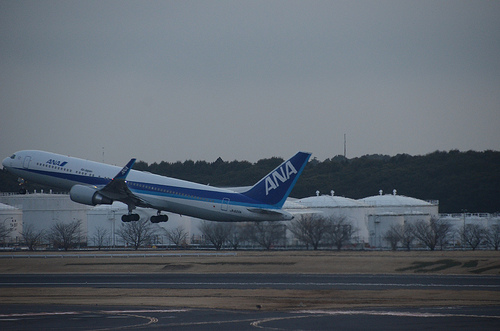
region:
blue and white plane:
[25, 145, 300, 241]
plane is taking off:
[7, 141, 294, 241]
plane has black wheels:
[112, 202, 183, 241]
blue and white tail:
[207, 146, 309, 210]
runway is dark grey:
[108, 250, 438, 294]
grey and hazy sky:
[226, 27, 358, 137]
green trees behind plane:
[245, 156, 479, 213]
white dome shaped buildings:
[306, 186, 416, 231]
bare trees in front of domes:
[13, 216, 468, 249]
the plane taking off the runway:
[9, 142, 311, 236]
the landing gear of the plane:
[122, 208, 163, 233]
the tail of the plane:
[236, 146, 316, 219]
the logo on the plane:
[34, 154, 67, 171]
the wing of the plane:
[102, 145, 143, 193]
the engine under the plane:
[65, 180, 108, 206]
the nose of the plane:
[0, 153, 7, 169]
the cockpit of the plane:
[6, 149, 35, 161]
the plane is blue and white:
[5, 145, 321, 240]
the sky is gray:
[42, 19, 494, 120]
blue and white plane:
[27, 121, 312, 225]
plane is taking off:
[22, 123, 264, 243]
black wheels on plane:
[115, 191, 183, 231]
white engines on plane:
[74, 173, 149, 205]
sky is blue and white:
[64, 20, 171, 134]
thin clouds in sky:
[64, 20, 321, 137]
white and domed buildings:
[304, 188, 425, 238]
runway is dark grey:
[81, 267, 342, 284]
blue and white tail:
[227, 148, 311, 225]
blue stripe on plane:
[24, 151, 226, 225]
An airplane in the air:
[0, 149, 314, 221]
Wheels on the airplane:
[121, 213, 171, 221]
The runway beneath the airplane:
[0, 273, 496, 286]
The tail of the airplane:
[243, 151, 311, 203]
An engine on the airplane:
[67, 183, 97, 205]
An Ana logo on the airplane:
[44, 156, 70, 166]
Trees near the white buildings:
[0, 149, 497, 213]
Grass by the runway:
[0, 249, 496, 272]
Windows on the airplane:
[38, 160, 180, 193]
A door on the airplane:
[21, 157, 31, 165]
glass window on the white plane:
[40, 160, 45, 166]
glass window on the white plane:
[40, 160, 41, 165]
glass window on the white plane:
[40, 160, 42, 166]